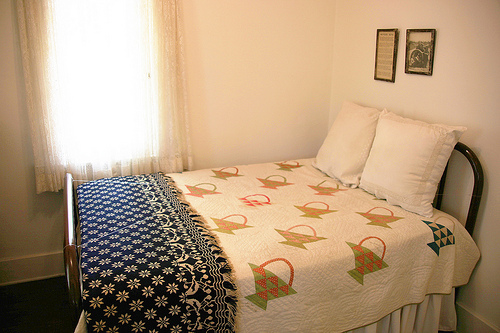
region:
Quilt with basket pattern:
[212, 181, 323, 232]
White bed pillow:
[381, 117, 430, 185]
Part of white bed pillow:
[337, 114, 358, 151]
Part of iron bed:
[466, 147, 484, 233]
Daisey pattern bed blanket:
[104, 214, 166, 284]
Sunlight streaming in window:
[57, 29, 140, 131]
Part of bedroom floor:
[32, 297, 57, 327]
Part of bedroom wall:
[228, 51, 283, 108]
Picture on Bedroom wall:
[377, 27, 397, 83]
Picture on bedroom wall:
[403, 26, 437, 79]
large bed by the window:
[64, 104, 482, 332]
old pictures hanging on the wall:
[371, 27, 437, 83]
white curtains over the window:
[19, 1, 191, 197]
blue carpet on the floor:
[0, 272, 87, 332]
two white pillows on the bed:
[313, 104, 463, 216]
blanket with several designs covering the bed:
[75, 156, 485, 329]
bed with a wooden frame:
[61, 136, 485, 329]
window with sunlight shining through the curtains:
[23, 0, 183, 194]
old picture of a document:
[371, 25, 399, 82]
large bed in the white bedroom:
[63, 131, 497, 331]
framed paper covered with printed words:
[373, 28, 399, 85]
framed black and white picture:
[403, 25, 436, 77]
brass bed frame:
[63, 138, 485, 330]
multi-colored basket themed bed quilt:
[163, 155, 479, 330]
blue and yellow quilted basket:
[420, 211, 455, 251]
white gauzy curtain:
[7, 0, 192, 195]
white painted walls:
[0, 0, 495, 330]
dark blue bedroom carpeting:
[0, 270, 77, 330]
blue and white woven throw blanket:
[76, 170, 239, 330]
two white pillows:
[311, 98, 466, 218]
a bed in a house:
[3, 54, 494, 326]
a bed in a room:
[11, 91, 498, 313]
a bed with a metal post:
[52, 66, 498, 331]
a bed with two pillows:
[96, 81, 453, 331]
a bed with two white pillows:
[132, 80, 478, 322]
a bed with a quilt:
[47, 86, 427, 332]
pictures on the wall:
[347, 8, 464, 83]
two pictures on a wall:
[354, 11, 463, 115]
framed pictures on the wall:
[328, 9, 465, 100]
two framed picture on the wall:
[364, 8, 489, 108]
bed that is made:
[39, 102, 486, 331]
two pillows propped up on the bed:
[300, 92, 463, 220]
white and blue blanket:
[75, 163, 252, 331]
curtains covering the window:
[16, 2, 200, 191]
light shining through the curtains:
[39, 1, 167, 169]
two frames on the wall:
[365, 16, 440, 88]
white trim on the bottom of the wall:
[3, 246, 68, 293]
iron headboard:
[430, 141, 487, 233]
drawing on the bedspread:
[241, 249, 300, 311]